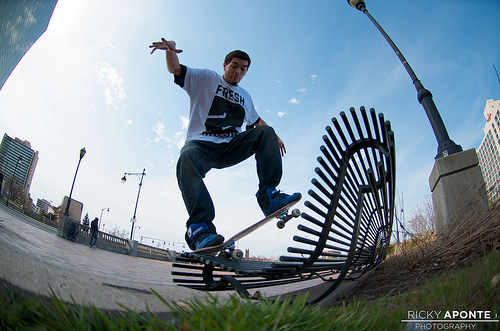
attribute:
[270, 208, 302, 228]
wheels — white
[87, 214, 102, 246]
person — walking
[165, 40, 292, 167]
shirt — white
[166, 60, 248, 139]
shirt — black, white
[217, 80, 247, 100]
writing — black